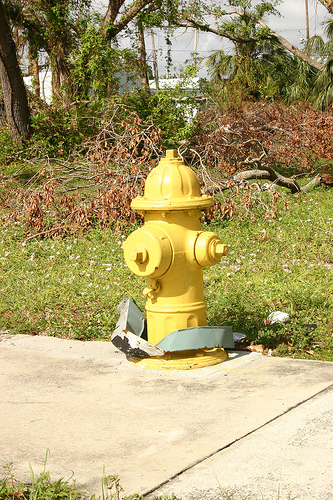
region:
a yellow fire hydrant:
[92, 131, 247, 366]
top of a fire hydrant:
[136, 131, 216, 211]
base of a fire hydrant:
[118, 309, 234, 383]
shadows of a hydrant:
[221, 326, 282, 359]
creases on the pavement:
[113, 351, 331, 497]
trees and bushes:
[62, 90, 329, 141]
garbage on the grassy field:
[255, 295, 317, 356]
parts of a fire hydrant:
[116, 219, 175, 278]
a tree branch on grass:
[178, 135, 323, 200]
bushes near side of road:
[6, 452, 174, 499]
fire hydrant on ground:
[112, 141, 233, 369]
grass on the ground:
[299, 278, 332, 354]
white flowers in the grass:
[79, 265, 96, 281]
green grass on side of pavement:
[20, 486, 60, 498]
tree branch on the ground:
[0, 106, 332, 241]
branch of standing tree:
[241, 3, 331, 107]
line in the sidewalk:
[128, 379, 332, 494]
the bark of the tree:
[0, 15, 36, 157]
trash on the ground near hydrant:
[113, 297, 153, 358]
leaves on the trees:
[80, 34, 106, 53]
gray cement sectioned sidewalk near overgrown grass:
[1, 329, 327, 495]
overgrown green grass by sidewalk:
[0, 157, 332, 360]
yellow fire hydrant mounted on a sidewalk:
[120, 148, 232, 369]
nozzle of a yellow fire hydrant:
[123, 229, 174, 279]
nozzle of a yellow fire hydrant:
[195, 229, 230, 271]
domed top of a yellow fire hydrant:
[130, 149, 216, 210]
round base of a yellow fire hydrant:
[131, 304, 231, 371]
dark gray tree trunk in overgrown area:
[0, 1, 38, 150]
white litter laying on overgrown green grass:
[264, 308, 294, 328]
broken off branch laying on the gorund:
[0, 102, 324, 241]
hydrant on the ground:
[102, 126, 252, 369]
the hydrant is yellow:
[113, 118, 240, 358]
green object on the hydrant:
[115, 294, 250, 357]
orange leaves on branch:
[8, 102, 327, 244]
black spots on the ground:
[41, 347, 332, 400]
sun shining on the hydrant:
[109, 118, 250, 372]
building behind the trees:
[24, 64, 216, 126]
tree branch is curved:
[204, 164, 312, 212]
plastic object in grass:
[259, 301, 296, 341]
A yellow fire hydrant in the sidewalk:
[93, 145, 242, 381]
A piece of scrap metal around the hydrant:
[104, 293, 238, 365]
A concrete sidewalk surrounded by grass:
[0, 333, 330, 497]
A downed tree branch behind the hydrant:
[22, 131, 324, 234]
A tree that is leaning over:
[190, 15, 329, 99]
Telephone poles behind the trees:
[140, 0, 325, 91]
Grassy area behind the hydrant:
[3, 165, 329, 334]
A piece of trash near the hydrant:
[260, 294, 297, 347]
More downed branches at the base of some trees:
[0, 87, 166, 151]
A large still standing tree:
[0, 0, 33, 150]